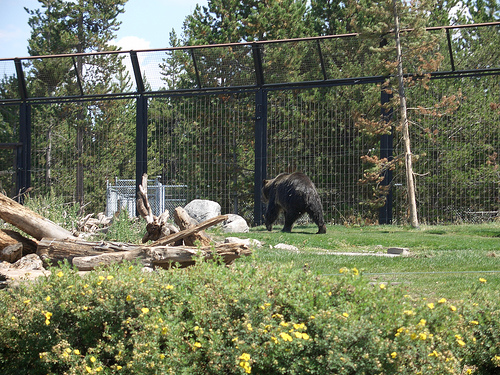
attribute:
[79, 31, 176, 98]
cloud — white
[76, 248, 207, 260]
logs — dead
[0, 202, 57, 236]
logs — dead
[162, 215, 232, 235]
logs — dead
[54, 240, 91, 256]
logs — dead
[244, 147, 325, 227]
bear — black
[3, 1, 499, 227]
trees — tall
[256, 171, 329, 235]
bear — walking, on all fours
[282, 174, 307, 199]
fur — black